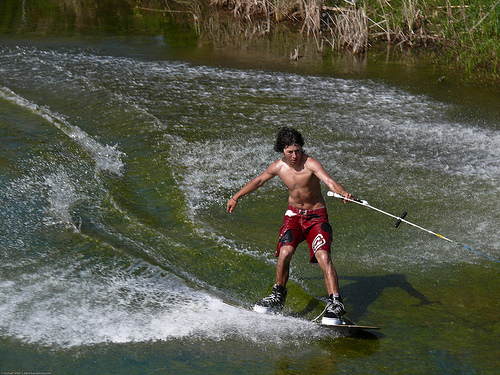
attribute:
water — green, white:
[0, 0, 499, 371]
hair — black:
[273, 127, 302, 149]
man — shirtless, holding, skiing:
[220, 120, 352, 329]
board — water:
[234, 308, 383, 333]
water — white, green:
[58, 153, 170, 309]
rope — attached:
[373, 204, 462, 262]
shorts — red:
[273, 207, 332, 266]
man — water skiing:
[226, 134, 378, 324]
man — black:
[254, 202, 349, 262]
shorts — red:
[277, 201, 336, 264]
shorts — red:
[275, 205, 333, 243]